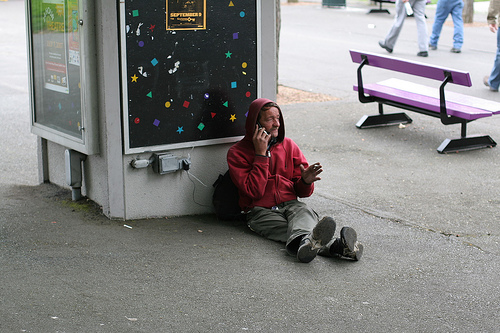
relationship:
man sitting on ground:
[232, 79, 472, 308] [6, 10, 495, 327]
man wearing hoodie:
[232, 79, 472, 308] [224, 97, 316, 211]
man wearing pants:
[232, 79, 472, 308] [247, 200, 329, 246]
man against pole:
[232, 79, 472, 308] [258, 1, 283, 103]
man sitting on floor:
[232, 79, 472, 308] [5, 1, 495, 327]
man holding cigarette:
[232, 79, 472, 308] [309, 160, 324, 169]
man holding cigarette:
[232, 79, 472, 308] [297, 156, 325, 178]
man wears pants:
[232, 79, 472, 308] [259, 204, 364, 270]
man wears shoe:
[232, 79, 472, 308] [339, 225, 365, 260]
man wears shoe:
[232, 79, 472, 308] [297, 215, 335, 262]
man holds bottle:
[373, 0, 435, 59] [402, 0, 421, 23]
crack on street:
[343, 192, 483, 255] [301, 105, 498, 262]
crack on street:
[343, 192, 483, 255] [391, 186, 491, 277]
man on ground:
[232, 79, 472, 308] [2, 168, 498, 329]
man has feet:
[232, 79, 472, 308] [303, 223, 334, 260]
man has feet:
[232, 79, 472, 308] [337, 217, 420, 264]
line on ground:
[318, 191, 487, 251] [311, 132, 444, 309]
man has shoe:
[232, 79, 472, 308] [297, 215, 335, 262]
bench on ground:
[344, 47, 486, 142] [279, 65, 498, 285]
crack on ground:
[426, 227, 463, 242] [6, 10, 495, 327]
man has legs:
[232, 79, 472, 308] [247, 203, 339, 253]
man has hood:
[232, 79, 472, 308] [245, 96, 285, 145]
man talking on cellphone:
[232, 79, 472, 308] [258, 125, 267, 140]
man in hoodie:
[232, 79, 472, 308] [224, 97, 316, 211]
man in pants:
[232, 79, 472, 308] [239, 197, 339, 252]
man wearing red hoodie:
[232, 79, 472, 308] [222, 94, 319, 205]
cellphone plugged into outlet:
[258, 125, 267, 140] [181, 155, 191, 172]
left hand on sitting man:
[294, 153, 326, 188] [232, 79, 472, 308]